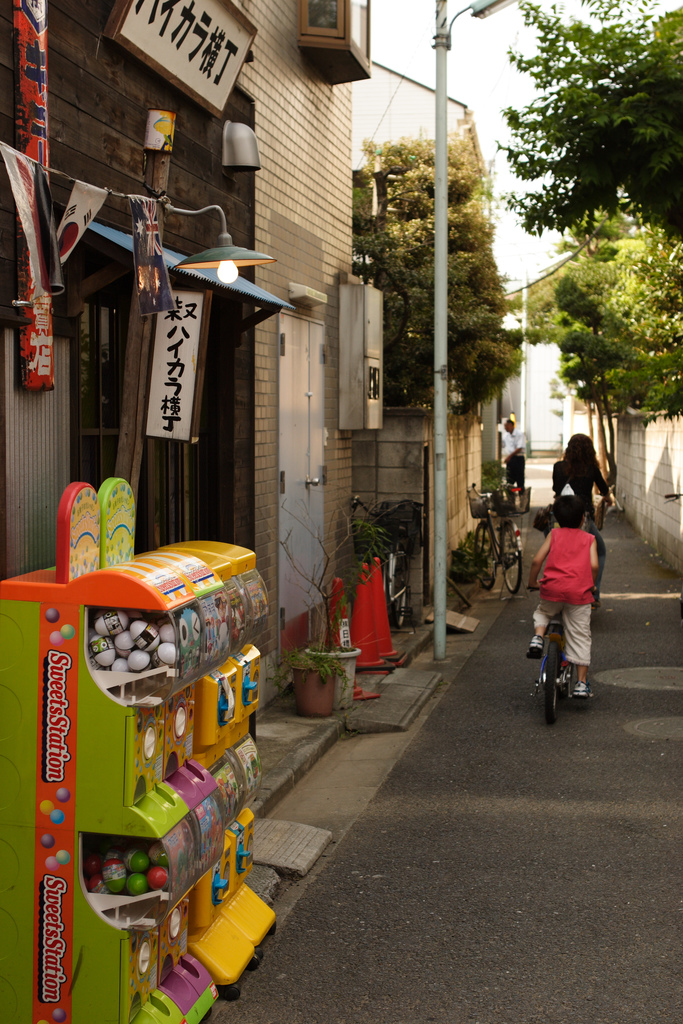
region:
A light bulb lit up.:
[208, 260, 241, 285]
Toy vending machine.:
[13, 467, 311, 1022]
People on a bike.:
[512, 471, 615, 717]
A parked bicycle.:
[457, 475, 540, 601]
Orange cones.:
[308, 529, 402, 690]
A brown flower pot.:
[292, 664, 337, 720]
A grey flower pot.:
[310, 652, 362, 701]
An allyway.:
[232, 484, 676, 1011]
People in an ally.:
[467, 385, 622, 740]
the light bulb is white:
[217, 260, 237, 283]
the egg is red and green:
[100, 856, 127, 892]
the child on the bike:
[524, 494, 599, 731]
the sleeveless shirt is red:
[537, 526, 598, 606]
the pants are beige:
[531, 589, 592, 668]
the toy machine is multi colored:
[2, 475, 278, 1019]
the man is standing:
[499, 417, 526, 494]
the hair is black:
[552, 493, 585, 528]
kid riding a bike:
[511, 487, 602, 728]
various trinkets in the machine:
[86, 599, 208, 709]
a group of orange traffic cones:
[316, 548, 401, 708]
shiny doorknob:
[305, 468, 325, 493]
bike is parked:
[464, 476, 540, 600]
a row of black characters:
[154, 293, 199, 439]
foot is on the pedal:
[524, 627, 543, 665]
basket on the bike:
[463, 482, 496, 521]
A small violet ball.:
[52, 787, 68, 800]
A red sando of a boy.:
[539, 526, 596, 606]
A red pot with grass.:
[275, 651, 346, 717]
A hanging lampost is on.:
[159, 197, 280, 284]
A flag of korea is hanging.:
[54, 178, 109, 264]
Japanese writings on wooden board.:
[144, 289, 210, 442]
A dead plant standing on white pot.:
[273, 494, 366, 707]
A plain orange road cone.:
[350, 561, 389, 678]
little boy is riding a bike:
[518, 480, 598, 728]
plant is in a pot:
[273, 479, 397, 721]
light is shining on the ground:
[595, 572, 682, 608]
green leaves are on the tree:
[338, 105, 527, 415]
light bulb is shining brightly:
[217, 252, 239, 284]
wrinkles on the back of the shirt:
[543, 556, 576, 588]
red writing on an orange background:
[44, 645, 72, 788]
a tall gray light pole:
[424, 0, 505, 660]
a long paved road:
[209, 441, 680, 1021]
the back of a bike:
[538, 615, 575, 720]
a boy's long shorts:
[532, 580, 595, 665]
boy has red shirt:
[507, 505, 604, 639]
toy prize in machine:
[94, 600, 128, 634]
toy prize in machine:
[86, 633, 113, 671]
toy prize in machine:
[109, 626, 139, 656]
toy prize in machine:
[111, 654, 131, 671]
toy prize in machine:
[123, 652, 157, 672]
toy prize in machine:
[129, 615, 164, 649]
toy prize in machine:
[154, 619, 183, 641]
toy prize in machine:
[149, 639, 183, 669]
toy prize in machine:
[102, 854, 127, 892]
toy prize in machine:
[123, 870, 150, 895]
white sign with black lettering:
[143, 282, 208, 445]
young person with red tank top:
[526, 493, 604, 707]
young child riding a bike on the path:
[520, 496, 600, 726]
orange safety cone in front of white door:
[349, 560, 389, 671]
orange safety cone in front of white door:
[327, 571, 356, 657]